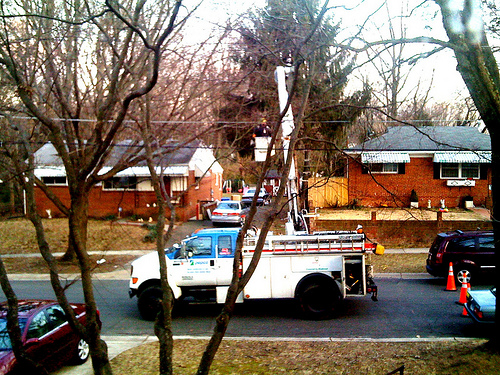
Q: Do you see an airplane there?
A: No, there are no airplanes.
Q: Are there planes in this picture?
A: No, there are no planes.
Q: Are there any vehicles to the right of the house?
A: Yes, there is a vehicle to the right of the house.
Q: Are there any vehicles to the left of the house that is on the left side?
A: No, the vehicle is to the right of the house.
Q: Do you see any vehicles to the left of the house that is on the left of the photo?
A: No, the vehicle is to the right of the house.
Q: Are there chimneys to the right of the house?
A: No, there is a vehicle to the right of the house.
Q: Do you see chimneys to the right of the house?
A: No, there is a vehicle to the right of the house.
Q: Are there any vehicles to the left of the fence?
A: Yes, there is a vehicle to the left of the fence.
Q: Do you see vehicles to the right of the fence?
A: No, the vehicle is to the left of the fence.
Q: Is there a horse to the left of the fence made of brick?
A: No, there is a vehicle to the left of the fence.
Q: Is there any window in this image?
A: Yes, there is a window.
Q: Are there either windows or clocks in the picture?
A: Yes, there is a window.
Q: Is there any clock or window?
A: Yes, there is a window.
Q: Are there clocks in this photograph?
A: No, there are no clocks.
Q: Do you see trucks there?
A: Yes, there is a truck.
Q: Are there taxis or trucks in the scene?
A: Yes, there is a truck.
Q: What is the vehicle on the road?
A: The vehicle is a truck.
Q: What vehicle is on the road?
A: The vehicle is a truck.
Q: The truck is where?
A: The truck is on the road.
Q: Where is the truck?
A: The truck is on the road.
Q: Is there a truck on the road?
A: Yes, there is a truck on the road.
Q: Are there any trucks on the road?
A: Yes, there is a truck on the road.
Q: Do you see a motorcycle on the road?
A: No, there is a truck on the road.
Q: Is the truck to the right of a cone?
A: No, the truck is to the left of a cone.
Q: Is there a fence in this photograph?
A: Yes, there is a fence.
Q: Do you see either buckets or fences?
A: Yes, there is a fence.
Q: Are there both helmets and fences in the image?
A: No, there is a fence but no helmets.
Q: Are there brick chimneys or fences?
A: Yes, there is a brick fence.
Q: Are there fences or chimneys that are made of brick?
A: Yes, the fence is made of brick.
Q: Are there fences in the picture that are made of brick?
A: Yes, there is a fence that is made of brick.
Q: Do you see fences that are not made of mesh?
A: Yes, there is a fence that is made of brick.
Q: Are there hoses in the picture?
A: No, there are no hoses.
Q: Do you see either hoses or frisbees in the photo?
A: No, there are no hoses or frisbees.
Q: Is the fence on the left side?
A: No, the fence is on the right of the image.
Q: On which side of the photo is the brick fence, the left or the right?
A: The fence is on the right of the image.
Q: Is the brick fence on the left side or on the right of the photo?
A: The fence is on the right of the image.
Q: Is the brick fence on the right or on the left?
A: The fence is on the right of the image.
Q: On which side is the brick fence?
A: The fence is on the right of the image.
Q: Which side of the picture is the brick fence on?
A: The fence is on the right of the image.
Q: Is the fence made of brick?
A: Yes, the fence is made of brick.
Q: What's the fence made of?
A: The fence is made of brick.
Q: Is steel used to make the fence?
A: No, the fence is made of brick.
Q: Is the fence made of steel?
A: No, the fence is made of brick.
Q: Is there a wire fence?
A: No, there is a fence but it is made of brick.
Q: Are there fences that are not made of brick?
A: No, there is a fence but it is made of brick.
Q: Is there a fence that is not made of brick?
A: No, there is a fence but it is made of brick.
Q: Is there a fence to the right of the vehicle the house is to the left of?
A: Yes, there is a fence to the right of the vehicle.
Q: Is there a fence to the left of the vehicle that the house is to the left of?
A: No, the fence is to the right of the vehicle.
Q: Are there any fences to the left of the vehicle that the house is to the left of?
A: No, the fence is to the right of the vehicle.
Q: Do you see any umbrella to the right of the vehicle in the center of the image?
A: No, there is a fence to the right of the vehicle.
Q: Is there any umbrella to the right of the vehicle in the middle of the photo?
A: No, there is a fence to the right of the vehicle.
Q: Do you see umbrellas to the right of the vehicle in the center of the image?
A: No, there is a fence to the right of the vehicle.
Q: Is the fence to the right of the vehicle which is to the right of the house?
A: Yes, the fence is to the right of the vehicle.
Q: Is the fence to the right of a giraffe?
A: No, the fence is to the right of the vehicle.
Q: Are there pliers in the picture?
A: No, there are no pliers.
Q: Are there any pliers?
A: No, there are no pliers.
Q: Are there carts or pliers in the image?
A: No, there are no pliers or carts.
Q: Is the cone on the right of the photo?
A: Yes, the cone is on the right of the image.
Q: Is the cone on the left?
A: No, the cone is on the right of the image.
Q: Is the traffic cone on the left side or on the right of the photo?
A: The traffic cone is on the right of the image.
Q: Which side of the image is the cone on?
A: The cone is on the right of the image.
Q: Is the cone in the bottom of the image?
A: Yes, the cone is in the bottom of the image.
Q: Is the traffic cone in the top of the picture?
A: No, the traffic cone is in the bottom of the image.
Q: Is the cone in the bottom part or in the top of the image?
A: The cone is in the bottom of the image.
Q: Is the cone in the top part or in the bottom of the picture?
A: The cone is in the bottom of the image.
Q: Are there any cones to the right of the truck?
A: Yes, there is a cone to the right of the truck.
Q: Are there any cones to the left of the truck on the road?
A: No, the cone is to the right of the truck.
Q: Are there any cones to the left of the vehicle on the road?
A: No, the cone is to the right of the truck.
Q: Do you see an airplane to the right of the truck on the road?
A: No, there is a cone to the right of the truck.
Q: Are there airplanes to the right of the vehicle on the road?
A: No, there is a cone to the right of the truck.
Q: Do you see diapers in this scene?
A: No, there are no diapers.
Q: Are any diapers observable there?
A: No, there are no diapers.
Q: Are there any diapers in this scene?
A: No, there are no diapers.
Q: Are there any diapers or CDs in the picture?
A: No, there are no diapers or cds.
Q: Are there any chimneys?
A: No, there are no chimneys.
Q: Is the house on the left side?
A: Yes, the house is on the left of the image.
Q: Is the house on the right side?
A: No, the house is on the left of the image.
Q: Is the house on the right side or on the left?
A: The house is on the left of the image.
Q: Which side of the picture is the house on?
A: The house is on the left of the image.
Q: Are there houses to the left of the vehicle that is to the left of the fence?
A: Yes, there is a house to the left of the vehicle.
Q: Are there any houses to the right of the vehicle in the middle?
A: No, the house is to the left of the vehicle.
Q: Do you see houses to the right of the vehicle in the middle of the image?
A: No, the house is to the left of the vehicle.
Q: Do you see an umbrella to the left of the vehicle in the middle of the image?
A: No, there is a house to the left of the vehicle.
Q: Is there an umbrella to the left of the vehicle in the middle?
A: No, there is a house to the left of the vehicle.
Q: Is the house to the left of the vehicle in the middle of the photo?
A: Yes, the house is to the left of the vehicle.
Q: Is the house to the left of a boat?
A: No, the house is to the left of the vehicle.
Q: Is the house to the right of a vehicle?
A: No, the house is to the left of a vehicle.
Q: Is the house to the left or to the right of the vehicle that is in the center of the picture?
A: The house is to the left of the vehicle.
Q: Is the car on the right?
A: No, the car is on the left of the image.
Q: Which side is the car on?
A: The car is on the left of the image.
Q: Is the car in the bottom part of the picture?
A: Yes, the car is in the bottom of the image.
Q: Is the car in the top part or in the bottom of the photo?
A: The car is in the bottom of the image.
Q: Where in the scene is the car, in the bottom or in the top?
A: The car is in the bottom of the image.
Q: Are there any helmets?
A: No, there are no helmets.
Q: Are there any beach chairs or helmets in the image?
A: No, there are no helmets or beach chairs.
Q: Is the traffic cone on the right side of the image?
A: Yes, the traffic cone is on the right of the image.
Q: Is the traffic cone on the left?
A: No, the traffic cone is on the right of the image.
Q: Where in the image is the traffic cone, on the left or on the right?
A: The traffic cone is on the right of the image.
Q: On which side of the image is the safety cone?
A: The safety cone is on the right of the image.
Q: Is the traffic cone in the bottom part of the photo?
A: Yes, the traffic cone is in the bottom of the image.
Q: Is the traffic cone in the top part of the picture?
A: No, the traffic cone is in the bottom of the image.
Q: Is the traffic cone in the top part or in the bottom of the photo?
A: The traffic cone is in the bottom of the image.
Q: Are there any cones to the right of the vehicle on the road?
A: Yes, there is a cone to the right of the truck.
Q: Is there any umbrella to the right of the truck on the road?
A: No, there is a cone to the right of the truck.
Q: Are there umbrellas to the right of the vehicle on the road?
A: No, there is a cone to the right of the truck.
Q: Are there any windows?
A: Yes, there is a window.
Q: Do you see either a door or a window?
A: Yes, there is a window.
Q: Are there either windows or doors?
A: Yes, there is a window.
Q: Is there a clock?
A: No, there are no clocks.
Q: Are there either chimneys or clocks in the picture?
A: No, there are no clocks or chimneys.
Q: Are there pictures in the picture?
A: No, there are no pictures.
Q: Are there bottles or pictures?
A: No, there are no pictures or bottles.